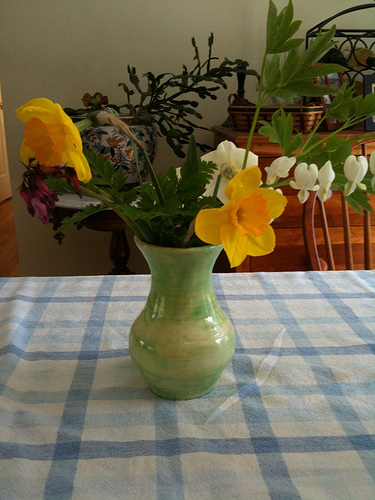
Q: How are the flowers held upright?
A: Vase.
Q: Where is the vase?
A: On table.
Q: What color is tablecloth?
A: Blue and white.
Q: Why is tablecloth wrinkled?
A: Not ironed.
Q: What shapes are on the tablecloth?
A: Rectangles.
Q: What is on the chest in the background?
A: Basket.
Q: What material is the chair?
A: Wood.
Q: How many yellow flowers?
A: Two.